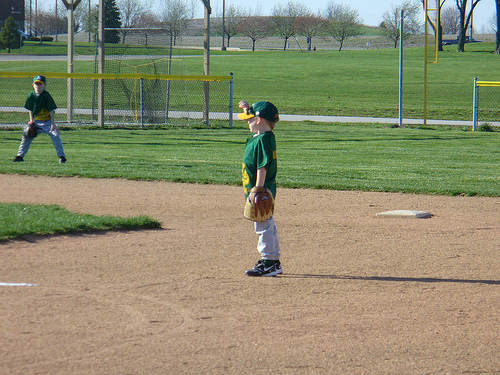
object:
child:
[237, 101, 283, 277]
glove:
[243, 186, 275, 222]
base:
[375, 209, 431, 218]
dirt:
[0, 173, 500, 375]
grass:
[0, 204, 161, 243]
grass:
[1, 41, 499, 199]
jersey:
[241, 131, 278, 204]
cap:
[237, 101, 279, 123]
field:
[1, 37, 500, 374]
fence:
[0, 73, 234, 129]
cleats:
[244, 259, 277, 277]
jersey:
[24, 89, 58, 121]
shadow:
[273, 273, 500, 284]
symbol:
[264, 265, 274, 271]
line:
[0, 282, 36, 286]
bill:
[237, 112, 255, 120]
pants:
[254, 216, 281, 260]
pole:
[97, 0, 104, 129]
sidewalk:
[0, 106, 500, 128]